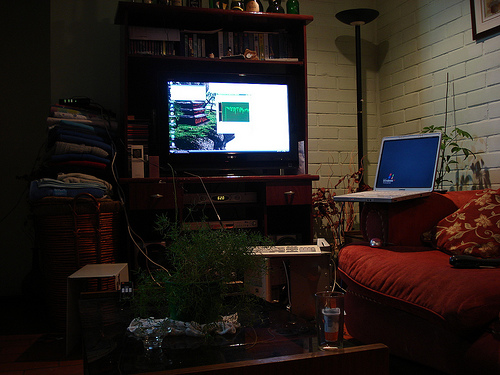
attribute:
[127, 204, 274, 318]
plant — potted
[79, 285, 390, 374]
table — wood, glass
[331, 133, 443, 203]
laptop — silver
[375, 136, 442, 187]
screen — blue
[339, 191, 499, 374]
couch — red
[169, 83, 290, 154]
screen — large, flat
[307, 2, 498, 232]
wall — white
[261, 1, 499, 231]
brick — white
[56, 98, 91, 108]
box — black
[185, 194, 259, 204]
box — silver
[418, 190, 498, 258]
pillow — red, gold, floral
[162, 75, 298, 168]
tv — flat, on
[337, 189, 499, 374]
sofa — red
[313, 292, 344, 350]
glass — empty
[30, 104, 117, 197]
clothes — stacked, piled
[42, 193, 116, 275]
basket — wicker, tall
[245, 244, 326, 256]
keyboard — white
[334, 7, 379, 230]
lamp — metal, off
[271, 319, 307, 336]
dish — glass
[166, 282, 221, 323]
pot — green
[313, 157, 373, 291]
plant — tall, red